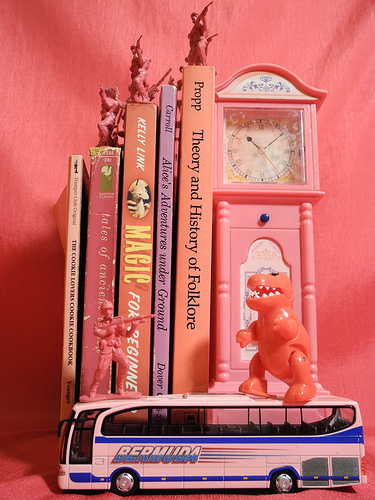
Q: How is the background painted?
A: Bright pink.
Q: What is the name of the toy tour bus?
A: Bermuda.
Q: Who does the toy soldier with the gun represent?
A: Soldier man.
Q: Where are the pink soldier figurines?
A: On top of books.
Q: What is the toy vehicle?
A: Bus.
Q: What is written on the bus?
A: Bermuda.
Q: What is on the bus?
A: Dinosaur.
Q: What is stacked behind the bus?
A: Books.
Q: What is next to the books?
A: Clock.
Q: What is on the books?
A: Toy soldiers.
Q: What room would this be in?
A: Bedroom.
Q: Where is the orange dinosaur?
A: On top of the bus.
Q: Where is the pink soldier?
A: On top of the bus.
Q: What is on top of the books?
A: A group of toy soldiers.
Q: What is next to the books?
A: A pink grandfather clock.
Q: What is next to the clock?
A: A group of books.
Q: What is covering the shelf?
A: A pink fuzzy cloth.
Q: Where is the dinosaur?
A: On the bus.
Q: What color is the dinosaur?
A: Orange.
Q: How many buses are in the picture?
A: One.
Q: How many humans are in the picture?
A: Zero.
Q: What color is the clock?
A: Pink.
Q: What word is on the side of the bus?
A: Bermuda.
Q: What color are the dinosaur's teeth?
A: White.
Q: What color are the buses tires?
A: Black.